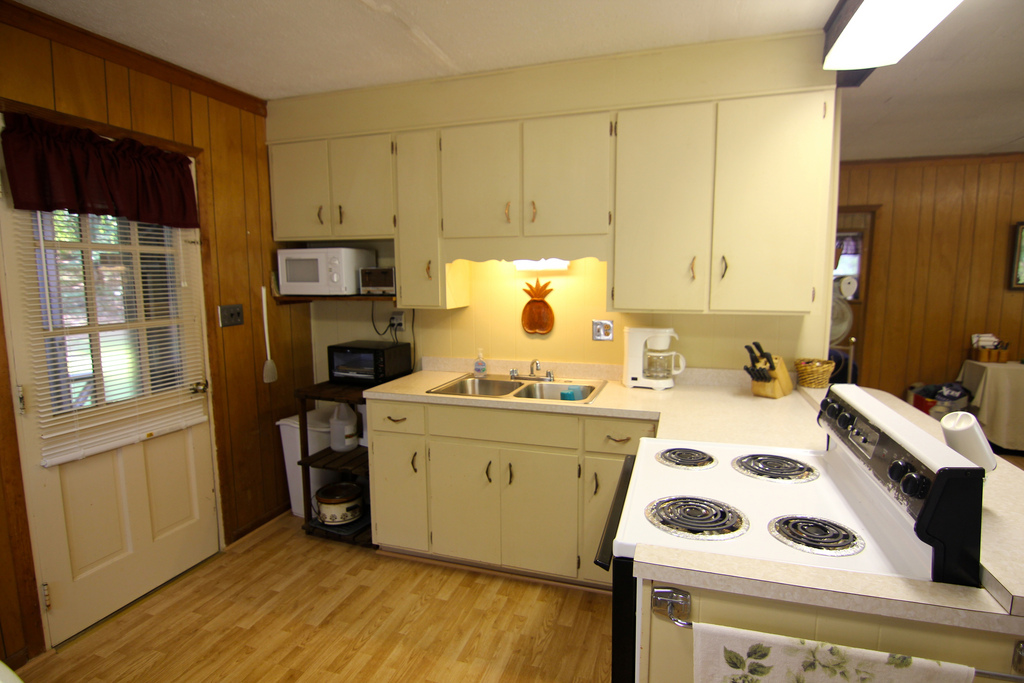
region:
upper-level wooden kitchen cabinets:
[268, 79, 837, 317]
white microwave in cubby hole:
[277, 241, 375, 300]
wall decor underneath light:
[520, 282, 556, 336]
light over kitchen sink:
[508, 256, 576, 280]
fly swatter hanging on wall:
[255, 284, 284, 390]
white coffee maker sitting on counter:
[619, 323, 693, 391]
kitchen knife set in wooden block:
[730, 334, 800, 407]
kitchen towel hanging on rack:
[688, 620, 1022, 679]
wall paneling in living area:
[840, 154, 1022, 404]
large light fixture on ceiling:
[818, 0, 971, 76]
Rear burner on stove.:
[764, 508, 863, 560]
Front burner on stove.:
[654, 438, 719, 476]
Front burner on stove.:
[641, 489, 747, 541]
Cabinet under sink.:
[420, 435, 503, 565]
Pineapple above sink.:
[509, 277, 560, 342]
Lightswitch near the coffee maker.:
[578, 311, 616, 346]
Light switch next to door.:
[211, 301, 251, 330]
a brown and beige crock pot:
[307, 475, 368, 529]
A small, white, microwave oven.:
[269, 243, 377, 300]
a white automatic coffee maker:
[617, 319, 687, 390]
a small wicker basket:
[793, 349, 836, 394]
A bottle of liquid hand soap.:
[469, 346, 488, 381]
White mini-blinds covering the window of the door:
[6, 193, 209, 468]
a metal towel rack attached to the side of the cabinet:
[642, 581, 1022, 676]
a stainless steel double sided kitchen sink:
[421, 351, 605, 405]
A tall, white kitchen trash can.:
[267, 403, 331, 521]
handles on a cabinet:
[582, 416, 627, 448]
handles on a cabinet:
[453, 437, 517, 498]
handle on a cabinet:
[362, 393, 416, 433]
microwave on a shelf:
[258, 238, 364, 296]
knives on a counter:
[713, 332, 787, 400]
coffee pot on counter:
[618, 308, 682, 392]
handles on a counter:
[665, 239, 752, 304]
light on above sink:
[499, 243, 569, 289]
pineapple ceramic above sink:
[513, 273, 562, 340]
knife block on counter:
[733, 331, 792, 408]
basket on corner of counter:
[779, 346, 838, 395]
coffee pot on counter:
[610, 309, 690, 396]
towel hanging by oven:
[676, 606, 977, 680]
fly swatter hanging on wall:
[251, 286, 289, 391]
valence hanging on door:
[3, 96, 201, 239]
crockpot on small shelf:
[313, 472, 358, 530]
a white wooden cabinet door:
[727, 115, 822, 300]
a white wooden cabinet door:
[638, 115, 695, 289]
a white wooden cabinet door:
[449, 122, 536, 250]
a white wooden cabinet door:
[398, 105, 475, 311]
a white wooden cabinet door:
[276, 143, 333, 235]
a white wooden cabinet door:
[372, 432, 467, 573]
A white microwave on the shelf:
[266, 243, 368, 300]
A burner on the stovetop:
[648, 484, 750, 549]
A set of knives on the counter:
[736, 333, 795, 410]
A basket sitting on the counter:
[795, 350, 843, 389]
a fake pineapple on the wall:
[517, 274, 568, 341]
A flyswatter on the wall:
[253, 276, 288, 391]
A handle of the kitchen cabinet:
[713, 249, 739, 292]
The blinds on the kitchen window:
[16, 218, 194, 466]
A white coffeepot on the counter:
[619, 320, 687, 393]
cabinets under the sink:
[401, 421, 608, 565]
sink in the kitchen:
[441, 329, 613, 443]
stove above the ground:
[600, 417, 888, 598]